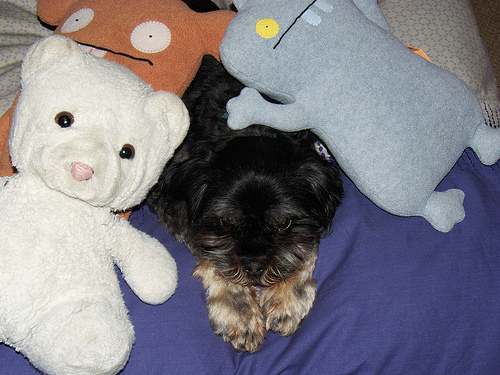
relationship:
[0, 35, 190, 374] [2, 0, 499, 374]
stuffed animal on top of bed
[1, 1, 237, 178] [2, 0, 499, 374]
stuffed animal on top of bed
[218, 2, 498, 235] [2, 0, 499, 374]
stuffed animal on top of bed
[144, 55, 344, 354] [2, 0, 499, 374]
dog on top of bed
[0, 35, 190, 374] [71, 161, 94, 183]
stuffed animal has nose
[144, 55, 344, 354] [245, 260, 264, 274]
dog has nose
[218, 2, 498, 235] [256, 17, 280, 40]
stuffed animal has eye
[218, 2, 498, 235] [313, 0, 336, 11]
stuffed animal has tooth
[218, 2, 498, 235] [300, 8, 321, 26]
stuffed animal has tooth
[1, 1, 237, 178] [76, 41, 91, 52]
stuffed animal has tooth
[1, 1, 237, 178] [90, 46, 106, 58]
stuffed animal has tooth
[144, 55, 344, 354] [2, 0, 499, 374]
dog laying on bed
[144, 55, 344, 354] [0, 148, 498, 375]
dog laying on blanket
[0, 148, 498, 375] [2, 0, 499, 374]
blanket on bed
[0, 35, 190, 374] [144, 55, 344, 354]
stuffed animal by dog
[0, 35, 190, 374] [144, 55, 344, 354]
stuffed animal on top of dog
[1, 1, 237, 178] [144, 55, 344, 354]
stuffed animal on top of dog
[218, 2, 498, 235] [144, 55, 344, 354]
stuffed animal on top of dog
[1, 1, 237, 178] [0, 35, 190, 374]
stuffed animal behind stuffed animal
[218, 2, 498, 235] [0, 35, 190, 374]
stuffed animal behind stuffed animal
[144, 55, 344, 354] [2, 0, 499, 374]
dog sleeping on bed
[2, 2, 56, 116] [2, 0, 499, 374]
pillow on top of bed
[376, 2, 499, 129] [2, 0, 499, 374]
pillow on top of bed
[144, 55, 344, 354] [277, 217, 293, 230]
dog has eye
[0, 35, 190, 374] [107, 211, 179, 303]
stuffed animal has arm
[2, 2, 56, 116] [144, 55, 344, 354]
pillow behind dog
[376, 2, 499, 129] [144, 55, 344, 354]
pillow behind dog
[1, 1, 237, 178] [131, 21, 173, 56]
stuffed animal has eye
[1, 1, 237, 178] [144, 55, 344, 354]
stuffed animal behind dog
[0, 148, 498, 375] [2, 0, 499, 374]
blanket on top of bed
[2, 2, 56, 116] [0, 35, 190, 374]
pillow underneath stuffed animal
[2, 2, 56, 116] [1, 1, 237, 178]
pillow underneath stuffed animal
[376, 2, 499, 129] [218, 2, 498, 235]
pillow underneath stuffed animal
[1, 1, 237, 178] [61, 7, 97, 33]
stuffed animal has eye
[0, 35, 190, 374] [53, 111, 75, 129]
stuffed animal has eye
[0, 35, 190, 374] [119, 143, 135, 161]
stuffed animal has eye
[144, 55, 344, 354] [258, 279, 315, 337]
dog has paw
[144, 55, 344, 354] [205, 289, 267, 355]
dog has paw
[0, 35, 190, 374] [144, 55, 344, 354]
stuffed animal covering dog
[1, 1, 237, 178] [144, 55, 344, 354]
stuffed animal covering dog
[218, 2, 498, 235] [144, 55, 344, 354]
stuffed animal covering dog